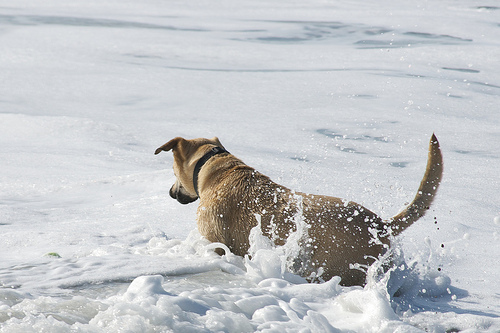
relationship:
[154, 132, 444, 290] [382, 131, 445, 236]
dog has a brown tail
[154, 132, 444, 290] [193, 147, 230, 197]
dog has a black collar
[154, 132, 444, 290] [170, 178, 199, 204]
dog has a black snout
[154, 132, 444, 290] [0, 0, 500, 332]
dog in snow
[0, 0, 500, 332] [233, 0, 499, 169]
snow has tracks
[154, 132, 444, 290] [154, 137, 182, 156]
dog has an ear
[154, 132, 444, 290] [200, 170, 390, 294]
dog has wet fur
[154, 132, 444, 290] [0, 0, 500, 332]
dog going through snow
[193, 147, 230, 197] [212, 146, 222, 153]
black collar has a buckle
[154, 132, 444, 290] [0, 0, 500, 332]
dog stuck in snow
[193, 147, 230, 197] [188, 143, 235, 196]
black collar around on dog neck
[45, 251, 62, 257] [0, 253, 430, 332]
tennis ball in water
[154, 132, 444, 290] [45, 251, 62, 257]
dog fetching tennis ball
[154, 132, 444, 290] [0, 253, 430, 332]
dog in water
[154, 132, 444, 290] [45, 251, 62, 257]
dog retrieving tennis ball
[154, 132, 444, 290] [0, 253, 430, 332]
dog in shallow water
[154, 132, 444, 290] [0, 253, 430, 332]
dog moving through water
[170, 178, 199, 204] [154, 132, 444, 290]
black snout on dog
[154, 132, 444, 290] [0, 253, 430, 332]
dog looking at water